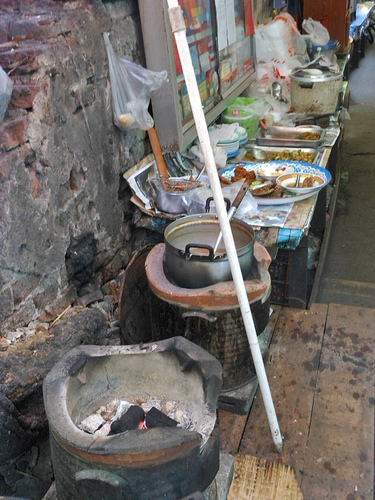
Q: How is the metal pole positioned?
A: Leaning on wall.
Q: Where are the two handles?
A: On pot.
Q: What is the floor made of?
A: Wood.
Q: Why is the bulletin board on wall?
A: To display announcements.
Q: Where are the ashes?
A: Fire pit.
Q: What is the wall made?
A: Bricks.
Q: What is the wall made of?
A: Bricks and cement.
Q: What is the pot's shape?
A: Round.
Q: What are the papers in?
A: Display case.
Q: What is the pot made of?
A: Silver.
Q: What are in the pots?
A: Food.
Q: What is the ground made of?
A: Brick.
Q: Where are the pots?
A: Out on the open.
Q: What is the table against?
A: Wall.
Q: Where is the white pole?
A: Between the pots.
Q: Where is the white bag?
A: Hanging on the wall.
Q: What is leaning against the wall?
A: White stick.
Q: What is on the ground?
A: Wood planks.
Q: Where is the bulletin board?
A: Against the wall.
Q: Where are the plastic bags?
A: Near the white pot.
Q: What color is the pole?
A: White.